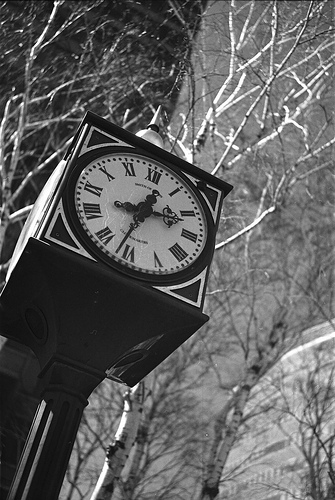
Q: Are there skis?
A: No, there are no skis.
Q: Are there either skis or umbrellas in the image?
A: No, there are no skis or umbrellas.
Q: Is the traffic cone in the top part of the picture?
A: Yes, the traffic cone is in the top of the image.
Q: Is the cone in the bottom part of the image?
A: No, the cone is in the top of the image.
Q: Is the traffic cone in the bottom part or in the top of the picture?
A: The traffic cone is in the top of the image.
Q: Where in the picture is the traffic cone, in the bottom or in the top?
A: The traffic cone is in the top of the image.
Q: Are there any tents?
A: No, there are no tents.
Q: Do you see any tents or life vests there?
A: No, there are no tents or life vests.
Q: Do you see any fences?
A: No, there are no fences.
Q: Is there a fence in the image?
A: No, there are no fences.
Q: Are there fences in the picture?
A: No, there are no fences.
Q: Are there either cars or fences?
A: No, there are no fences or cars.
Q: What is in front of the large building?
A: The tree is in front of the building.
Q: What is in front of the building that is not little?
A: The tree is in front of the building.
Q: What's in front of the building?
A: The tree is in front of the building.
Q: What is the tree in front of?
A: The tree is in front of the building.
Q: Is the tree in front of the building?
A: Yes, the tree is in front of the building.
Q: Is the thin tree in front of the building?
A: Yes, the tree is in front of the building.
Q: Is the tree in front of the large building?
A: Yes, the tree is in front of the building.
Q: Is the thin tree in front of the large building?
A: Yes, the tree is in front of the building.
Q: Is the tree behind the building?
A: No, the tree is in front of the building.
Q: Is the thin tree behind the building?
A: No, the tree is in front of the building.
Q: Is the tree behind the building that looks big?
A: No, the tree is in front of the building.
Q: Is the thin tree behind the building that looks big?
A: No, the tree is in front of the building.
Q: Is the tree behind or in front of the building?
A: The tree is in front of the building.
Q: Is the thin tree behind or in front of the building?
A: The tree is in front of the building.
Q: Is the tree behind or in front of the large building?
A: The tree is in front of the building.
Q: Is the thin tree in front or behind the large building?
A: The tree is in front of the building.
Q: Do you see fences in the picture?
A: No, there are no fences.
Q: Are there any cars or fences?
A: No, there are no fences or cars.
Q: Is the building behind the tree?
A: Yes, the building is behind the tree.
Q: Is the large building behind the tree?
A: Yes, the building is behind the tree.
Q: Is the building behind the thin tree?
A: Yes, the building is behind the tree.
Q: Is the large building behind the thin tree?
A: Yes, the building is behind the tree.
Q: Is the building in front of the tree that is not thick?
A: No, the building is behind the tree.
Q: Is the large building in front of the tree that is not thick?
A: No, the building is behind the tree.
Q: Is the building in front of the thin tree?
A: No, the building is behind the tree.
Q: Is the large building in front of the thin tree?
A: No, the building is behind the tree.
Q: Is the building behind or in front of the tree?
A: The building is behind the tree.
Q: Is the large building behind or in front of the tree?
A: The building is behind the tree.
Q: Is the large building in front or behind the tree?
A: The building is behind the tree.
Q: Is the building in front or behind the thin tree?
A: The building is behind the tree.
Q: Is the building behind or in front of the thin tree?
A: The building is behind the tree.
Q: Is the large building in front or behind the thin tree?
A: The building is behind the tree.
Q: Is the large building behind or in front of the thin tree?
A: The building is behind the tree.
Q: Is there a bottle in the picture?
A: No, there are no bottles.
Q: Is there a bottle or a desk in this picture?
A: No, there are no bottles or desks.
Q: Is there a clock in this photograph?
A: Yes, there is a clock.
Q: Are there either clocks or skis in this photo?
A: Yes, there is a clock.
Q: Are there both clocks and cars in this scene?
A: No, there is a clock but no cars.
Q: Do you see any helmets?
A: No, there are no helmets.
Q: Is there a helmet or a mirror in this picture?
A: No, there are no helmets or mirrors.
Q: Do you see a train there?
A: No, there are no trains.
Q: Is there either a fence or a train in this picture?
A: No, there are no trains or fences.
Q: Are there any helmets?
A: No, there are no helmets.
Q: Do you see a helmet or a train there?
A: No, there are no helmets or trains.